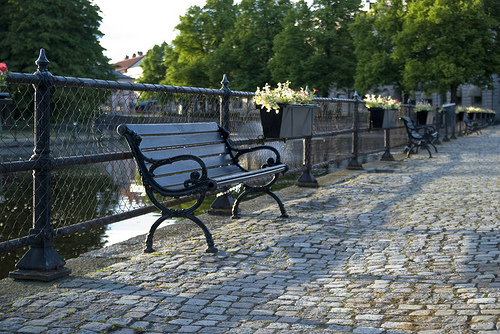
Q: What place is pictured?
A: It is a walkway.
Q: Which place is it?
A: It is a walkway.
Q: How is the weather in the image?
A: It is clear.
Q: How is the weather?
A: It is clear.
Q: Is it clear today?
A: Yes, it is clear.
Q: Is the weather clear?
A: Yes, it is clear.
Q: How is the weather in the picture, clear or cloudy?
A: It is clear.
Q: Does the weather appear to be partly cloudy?
A: No, it is clear.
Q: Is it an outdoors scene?
A: Yes, it is outdoors.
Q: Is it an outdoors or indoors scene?
A: It is outdoors.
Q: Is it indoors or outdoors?
A: It is outdoors.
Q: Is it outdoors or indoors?
A: It is outdoors.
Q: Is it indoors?
A: No, it is outdoors.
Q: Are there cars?
A: No, there are no cars.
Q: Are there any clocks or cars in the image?
A: No, there are no cars or clocks.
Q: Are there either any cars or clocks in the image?
A: No, there are no cars or clocks.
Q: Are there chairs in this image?
A: No, there are no chairs.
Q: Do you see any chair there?
A: No, there are no chairs.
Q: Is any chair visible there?
A: No, there are no chairs.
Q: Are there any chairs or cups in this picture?
A: No, there are no chairs or cups.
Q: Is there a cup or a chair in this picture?
A: No, there are no chairs or cups.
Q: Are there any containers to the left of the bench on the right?
A: Yes, there is a container to the left of the bench.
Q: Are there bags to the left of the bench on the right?
A: No, there is a container to the left of the bench.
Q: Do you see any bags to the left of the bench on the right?
A: No, there is a container to the left of the bench.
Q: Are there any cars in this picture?
A: No, there are no cars.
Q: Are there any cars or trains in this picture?
A: No, there are no cars or trains.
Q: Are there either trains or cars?
A: No, there are no cars or trains.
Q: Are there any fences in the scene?
A: Yes, there is a fence.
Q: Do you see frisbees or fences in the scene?
A: Yes, there is a fence.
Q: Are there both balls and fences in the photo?
A: No, there is a fence but no balls.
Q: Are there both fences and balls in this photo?
A: No, there is a fence but no balls.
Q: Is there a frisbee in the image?
A: No, there are no frisbees.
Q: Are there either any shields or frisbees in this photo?
A: No, there are no frisbees or shields.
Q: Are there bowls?
A: No, there are no bowls.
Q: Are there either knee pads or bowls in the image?
A: No, there are no bowls or knee pads.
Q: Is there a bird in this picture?
A: No, there are no birds.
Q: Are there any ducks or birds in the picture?
A: No, there are no birds or ducks.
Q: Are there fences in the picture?
A: Yes, there is a fence.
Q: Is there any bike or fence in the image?
A: Yes, there is a fence.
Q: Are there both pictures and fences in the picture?
A: No, there is a fence but no pictures.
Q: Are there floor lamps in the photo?
A: No, there are no floor lamps.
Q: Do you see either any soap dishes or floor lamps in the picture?
A: No, there are no floor lamps or soap dishes.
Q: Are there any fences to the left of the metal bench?
A: Yes, there is a fence to the left of the bench.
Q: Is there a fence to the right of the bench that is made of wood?
A: No, the fence is to the left of the bench.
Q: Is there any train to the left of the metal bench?
A: No, there is a fence to the left of the bench.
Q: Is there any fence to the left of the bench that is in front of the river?
A: Yes, there is a fence to the left of the bench.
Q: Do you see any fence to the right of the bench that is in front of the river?
A: No, the fence is to the left of the bench.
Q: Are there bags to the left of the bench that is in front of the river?
A: No, there is a fence to the left of the bench.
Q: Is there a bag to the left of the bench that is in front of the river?
A: No, there is a fence to the left of the bench.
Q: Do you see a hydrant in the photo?
A: No, there are no fire hydrants.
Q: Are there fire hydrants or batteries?
A: No, there are no fire hydrants or batteries.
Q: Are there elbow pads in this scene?
A: No, there are no elbow pads.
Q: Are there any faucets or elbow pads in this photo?
A: No, there are no elbow pads or faucets.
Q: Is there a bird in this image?
A: No, there are no birds.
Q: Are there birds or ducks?
A: No, there are no birds or ducks.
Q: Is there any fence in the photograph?
A: Yes, there is a fence.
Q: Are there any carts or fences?
A: Yes, there is a fence.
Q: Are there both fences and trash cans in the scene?
A: No, there is a fence but no trash cans.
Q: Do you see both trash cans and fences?
A: No, there is a fence but no trash cans.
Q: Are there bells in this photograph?
A: No, there are no bells.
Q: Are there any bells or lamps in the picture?
A: No, there are no bells or lamps.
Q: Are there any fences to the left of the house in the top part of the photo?
A: Yes, there is a fence to the left of the house.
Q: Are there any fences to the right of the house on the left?
A: No, the fence is to the left of the house.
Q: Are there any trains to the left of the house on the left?
A: No, there is a fence to the left of the house.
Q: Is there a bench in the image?
A: Yes, there is a bench.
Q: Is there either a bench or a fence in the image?
A: Yes, there is a bench.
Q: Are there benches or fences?
A: Yes, there is a bench.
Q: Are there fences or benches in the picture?
A: Yes, there is a bench.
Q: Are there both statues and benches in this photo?
A: No, there is a bench but no statues.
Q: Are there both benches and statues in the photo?
A: No, there is a bench but no statues.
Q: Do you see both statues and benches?
A: No, there is a bench but no statues.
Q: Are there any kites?
A: No, there are no kites.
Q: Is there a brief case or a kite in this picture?
A: No, there are no kites or briefcases.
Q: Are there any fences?
A: Yes, there is a fence.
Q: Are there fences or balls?
A: Yes, there is a fence.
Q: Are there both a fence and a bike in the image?
A: No, there is a fence but no bikes.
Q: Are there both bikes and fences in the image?
A: No, there is a fence but no bikes.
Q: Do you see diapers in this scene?
A: No, there are no diapers.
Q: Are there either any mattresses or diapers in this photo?
A: No, there are no diapers or mattresses.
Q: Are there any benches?
A: Yes, there is a bench.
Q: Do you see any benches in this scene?
A: Yes, there is a bench.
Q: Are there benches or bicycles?
A: Yes, there is a bench.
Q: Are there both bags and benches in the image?
A: No, there is a bench but no bags.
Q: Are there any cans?
A: No, there are no cans.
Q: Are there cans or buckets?
A: No, there are no cans or buckets.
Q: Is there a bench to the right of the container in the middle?
A: Yes, there is a bench to the right of the container.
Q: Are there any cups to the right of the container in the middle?
A: No, there is a bench to the right of the container.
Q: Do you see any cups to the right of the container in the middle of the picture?
A: No, there is a bench to the right of the container.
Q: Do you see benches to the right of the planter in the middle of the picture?
A: Yes, there is a bench to the right of the planter.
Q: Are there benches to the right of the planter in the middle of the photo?
A: Yes, there is a bench to the right of the planter.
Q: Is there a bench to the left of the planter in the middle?
A: No, the bench is to the right of the planter.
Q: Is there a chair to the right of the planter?
A: No, there is a bench to the right of the planter.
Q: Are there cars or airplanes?
A: No, there are no cars or airplanes.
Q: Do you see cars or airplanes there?
A: No, there are no cars or airplanes.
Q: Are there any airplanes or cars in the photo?
A: No, there are no cars or airplanes.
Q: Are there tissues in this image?
A: No, there are no tissues.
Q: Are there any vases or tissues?
A: No, there are no tissues or vases.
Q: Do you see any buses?
A: No, there are no buses.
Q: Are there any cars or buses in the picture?
A: No, there are no buses or cars.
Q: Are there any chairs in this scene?
A: No, there are no chairs.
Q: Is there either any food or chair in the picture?
A: No, there are no chairs or food.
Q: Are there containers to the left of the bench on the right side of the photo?
A: Yes, there is a container to the left of the bench.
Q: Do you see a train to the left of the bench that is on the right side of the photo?
A: No, there is a container to the left of the bench.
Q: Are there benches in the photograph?
A: Yes, there is a bench.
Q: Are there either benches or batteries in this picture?
A: Yes, there is a bench.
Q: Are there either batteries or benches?
A: Yes, there is a bench.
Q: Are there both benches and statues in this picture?
A: No, there is a bench but no statues.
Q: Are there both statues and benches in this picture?
A: No, there is a bench but no statues.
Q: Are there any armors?
A: No, there are no armors.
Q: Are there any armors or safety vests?
A: No, there are no armors or safety vests.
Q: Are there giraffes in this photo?
A: No, there are no giraffes.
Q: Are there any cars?
A: No, there are no cars.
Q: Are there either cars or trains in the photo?
A: No, there are no cars or trains.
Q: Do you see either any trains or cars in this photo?
A: No, there are no cars or trains.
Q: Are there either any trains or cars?
A: No, there are no cars or trains.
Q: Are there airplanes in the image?
A: No, there are no airplanes.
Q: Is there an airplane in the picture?
A: No, there are no airplanes.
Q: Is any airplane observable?
A: No, there are no airplanes.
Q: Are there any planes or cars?
A: No, there are no planes or cars.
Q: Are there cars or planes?
A: No, there are no planes or cars.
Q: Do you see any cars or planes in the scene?
A: No, there are no planes or cars.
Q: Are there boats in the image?
A: No, there are no boats.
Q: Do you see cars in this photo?
A: No, there are no cars.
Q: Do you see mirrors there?
A: No, there are no mirrors.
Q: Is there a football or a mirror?
A: No, there are no mirrors or footballs.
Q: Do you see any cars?
A: No, there are no cars.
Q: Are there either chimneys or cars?
A: No, there are no cars or chimneys.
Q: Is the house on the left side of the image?
A: Yes, the house is on the left of the image.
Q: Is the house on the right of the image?
A: No, the house is on the left of the image.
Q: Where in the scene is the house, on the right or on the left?
A: The house is on the left of the image.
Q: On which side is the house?
A: The house is on the left of the image.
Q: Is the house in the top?
A: Yes, the house is in the top of the image.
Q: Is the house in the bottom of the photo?
A: No, the house is in the top of the image.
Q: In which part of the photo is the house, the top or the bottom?
A: The house is in the top of the image.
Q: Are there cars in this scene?
A: No, there are no cars.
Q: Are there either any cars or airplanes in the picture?
A: No, there are no cars or airplanes.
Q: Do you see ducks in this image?
A: No, there are no ducks.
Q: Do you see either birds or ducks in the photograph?
A: No, there are no ducks or birds.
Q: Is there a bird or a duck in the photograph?
A: No, there are no ducks or birds.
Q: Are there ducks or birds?
A: No, there are no ducks or birds.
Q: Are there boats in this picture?
A: No, there are no boats.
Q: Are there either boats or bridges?
A: No, there are no boats or bridges.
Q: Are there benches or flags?
A: Yes, there is a bench.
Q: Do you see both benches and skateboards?
A: No, there is a bench but no skateboards.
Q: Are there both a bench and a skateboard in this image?
A: No, there is a bench but no skateboards.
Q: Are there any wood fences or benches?
A: Yes, there is a wood bench.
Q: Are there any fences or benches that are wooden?
A: Yes, the bench is wooden.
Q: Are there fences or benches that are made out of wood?
A: Yes, the bench is made of wood.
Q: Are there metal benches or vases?
A: Yes, there is a metal bench.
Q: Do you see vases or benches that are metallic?
A: Yes, the bench is metallic.